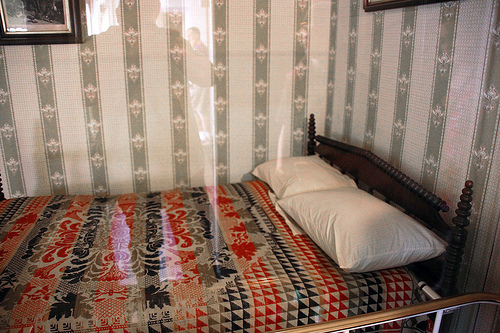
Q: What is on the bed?
A: Pillows.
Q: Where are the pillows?
A: On the bed.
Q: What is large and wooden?
A: Bed frame.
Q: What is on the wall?
A: A shadow.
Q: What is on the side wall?
A: A frame.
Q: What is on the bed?
A: Pillows.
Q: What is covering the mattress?
A: Blankets.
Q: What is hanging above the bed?
A: A frame.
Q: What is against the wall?
A: The headboard.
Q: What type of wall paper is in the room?
A: Striped.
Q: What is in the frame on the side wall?
A: A picture.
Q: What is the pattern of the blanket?
A: Triangles.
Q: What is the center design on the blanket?
A: A flower.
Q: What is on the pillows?
A: A pillow case.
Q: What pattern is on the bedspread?
A: Circular.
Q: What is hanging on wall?
A: Paintings.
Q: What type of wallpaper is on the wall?
A: Cream and green.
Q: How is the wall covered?
A: Papered.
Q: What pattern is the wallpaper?
A: Striped.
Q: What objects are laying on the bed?
A: Pillows.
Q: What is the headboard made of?
A: Wood.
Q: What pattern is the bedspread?
A: Horizontal checkers.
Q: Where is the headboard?
A: Against the wall.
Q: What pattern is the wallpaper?
A: Striped.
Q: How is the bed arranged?
A: The bed is made.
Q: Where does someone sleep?
A: In the bed.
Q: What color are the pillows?
A: White.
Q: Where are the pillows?
A: On the bed.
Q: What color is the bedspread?
A: Red, tan, and black.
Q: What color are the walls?
A: Gray and white.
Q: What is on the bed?
A: Pillows.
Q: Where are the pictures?
A: On the wall.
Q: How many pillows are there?
A: Two.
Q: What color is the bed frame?
A: Brown.